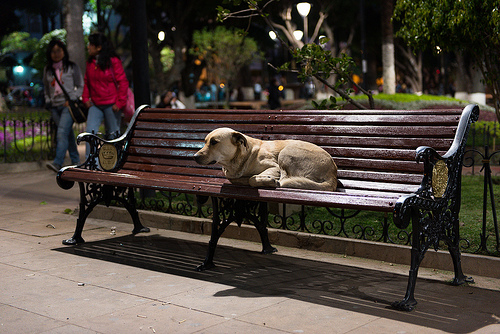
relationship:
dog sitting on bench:
[193, 125, 339, 202] [56, 105, 482, 307]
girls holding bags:
[44, 30, 127, 175] [65, 93, 109, 123]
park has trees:
[12, 5, 499, 287] [128, 15, 496, 87]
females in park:
[44, 30, 127, 175] [12, 5, 499, 287]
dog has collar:
[193, 125, 339, 202] [242, 148, 253, 172]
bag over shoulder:
[108, 71, 143, 116] [97, 55, 132, 78]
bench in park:
[56, 105, 482, 307] [12, 5, 499, 287]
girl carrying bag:
[74, 25, 140, 168] [108, 71, 143, 116]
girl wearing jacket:
[74, 25, 140, 168] [85, 63, 124, 105]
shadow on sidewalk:
[104, 227, 389, 296] [18, 247, 489, 333]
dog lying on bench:
[193, 125, 339, 202] [56, 105, 482, 307]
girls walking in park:
[44, 30, 127, 175] [12, 5, 499, 287]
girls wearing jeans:
[44, 30, 127, 175] [50, 112, 121, 154]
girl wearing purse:
[74, 25, 140, 168] [120, 90, 141, 118]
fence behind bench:
[95, 122, 494, 220] [56, 105, 482, 307]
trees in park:
[128, 15, 496, 87] [12, 5, 499, 287]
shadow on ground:
[104, 227, 389, 296] [30, 205, 495, 326]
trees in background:
[128, 15, 496, 87] [24, 13, 499, 93]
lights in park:
[257, 3, 324, 51] [12, 5, 499, 287]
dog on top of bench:
[193, 125, 339, 202] [56, 105, 482, 307]